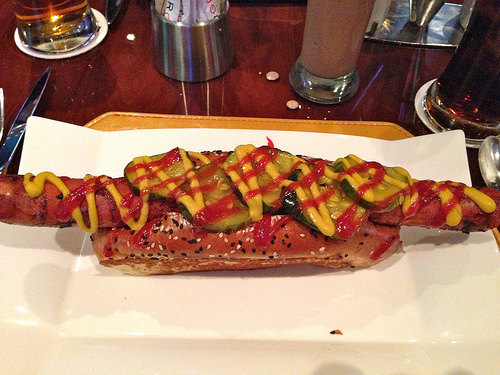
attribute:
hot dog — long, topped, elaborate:
[0, 172, 497, 234]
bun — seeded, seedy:
[93, 212, 402, 276]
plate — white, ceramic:
[1, 115, 499, 373]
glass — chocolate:
[288, 0, 380, 106]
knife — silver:
[1, 66, 52, 175]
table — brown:
[0, 1, 499, 374]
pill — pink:
[265, 70, 281, 81]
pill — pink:
[283, 99, 300, 111]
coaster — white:
[13, 8, 109, 60]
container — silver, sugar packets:
[150, 0, 233, 84]